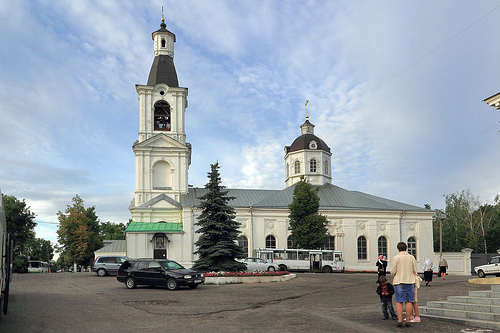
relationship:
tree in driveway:
[190, 160, 247, 271] [296, 266, 350, 277]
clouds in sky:
[272, 57, 273, 58] [35, 15, 89, 47]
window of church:
[147, 94, 176, 140] [205, 168, 488, 269]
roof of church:
[333, 185, 390, 208] [205, 168, 488, 269]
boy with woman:
[374, 280, 393, 319] [373, 251, 392, 279]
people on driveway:
[357, 237, 481, 328] [296, 266, 350, 277]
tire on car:
[159, 279, 179, 292] [106, 251, 212, 293]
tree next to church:
[190, 160, 247, 271] [205, 168, 488, 269]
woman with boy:
[373, 251, 392, 279] [374, 280, 393, 319]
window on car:
[147, 94, 176, 140] [106, 251, 212, 293]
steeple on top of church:
[283, 127, 332, 153] [205, 168, 488, 269]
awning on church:
[240, 199, 275, 214] [205, 168, 488, 269]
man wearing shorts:
[388, 257, 419, 282] [389, 281, 419, 307]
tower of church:
[120, 6, 182, 91] [205, 168, 488, 269]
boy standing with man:
[374, 280, 393, 319] [388, 257, 419, 282]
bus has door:
[248, 240, 325, 264] [310, 246, 316, 270]